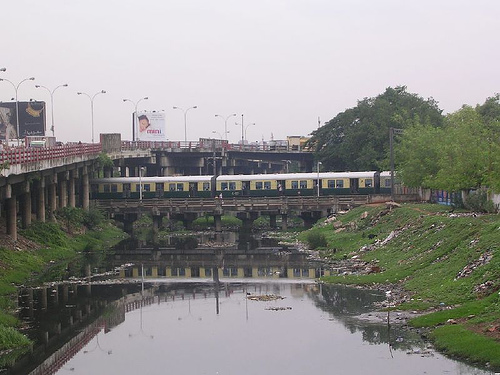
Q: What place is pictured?
A: It is a river.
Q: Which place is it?
A: It is a river.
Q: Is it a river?
A: Yes, it is a river.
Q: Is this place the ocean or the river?
A: It is the river.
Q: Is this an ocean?
A: No, it is a river.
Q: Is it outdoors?
A: Yes, it is outdoors.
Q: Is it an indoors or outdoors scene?
A: It is outdoors.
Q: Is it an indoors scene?
A: No, it is outdoors.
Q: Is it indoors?
A: No, it is outdoors.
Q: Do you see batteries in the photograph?
A: No, there are no batteries.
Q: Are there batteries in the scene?
A: No, there are no batteries.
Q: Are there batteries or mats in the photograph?
A: No, there are no batteries or mats.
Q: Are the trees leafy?
A: Yes, the trees are leafy.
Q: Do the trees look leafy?
A: Yes, the trees are leafy.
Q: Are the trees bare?
A: No, the trees are leafy.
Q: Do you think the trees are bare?
A: No, the trees are leafy.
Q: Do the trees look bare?
A: No, the trees are leafy.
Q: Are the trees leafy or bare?
A: The trees are leafy.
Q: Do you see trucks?
A: Yes, there is a truck.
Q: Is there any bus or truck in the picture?
A: Yes, there is a truck.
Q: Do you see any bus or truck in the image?
A: Yes, there is a truck.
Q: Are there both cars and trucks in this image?
A: Yes, there are both a truck and a car.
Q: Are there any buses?
A: No, there are no buses.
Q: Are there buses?
A: No, there are no buses.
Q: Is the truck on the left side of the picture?
A: Yes, the truck is on the left of the image.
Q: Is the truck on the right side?
A: No, the truck is on the left of the image.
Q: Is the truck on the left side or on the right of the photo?
A: The truck is on the left of the image.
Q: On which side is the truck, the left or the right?
A: The truck is on the left of the image.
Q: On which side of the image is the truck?
A: The truck is on the left of the image.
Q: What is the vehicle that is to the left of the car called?
A: The vehicle is a truck.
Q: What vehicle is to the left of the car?
A: The vehicle is a truck.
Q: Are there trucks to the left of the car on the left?
A: Yes, there is a truck to the left of the car.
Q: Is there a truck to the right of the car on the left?
A: No, the truck is to the left of the car.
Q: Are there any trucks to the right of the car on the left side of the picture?
A: No, the truck is to the left of the car.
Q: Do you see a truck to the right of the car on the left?
A: No, the truck is to the left of the car.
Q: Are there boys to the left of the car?
A: No, there is a truck to the left of the car.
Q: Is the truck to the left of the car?
A: Yes, the truck is to the left of the car.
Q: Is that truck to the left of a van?
A: No, the truck is to the left of the car.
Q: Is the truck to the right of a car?
A: No, the truck is to the left of a car.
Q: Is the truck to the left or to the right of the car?
A: The truck is to the left of the car.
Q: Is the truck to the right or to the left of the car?
A: The truck is to the left of the car.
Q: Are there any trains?
A: Yes, there is a train.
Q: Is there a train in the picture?
A: Yes, there is a train.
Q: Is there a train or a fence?
A: Yes, there is a train.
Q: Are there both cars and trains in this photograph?
A: Yes, there are both a train and a car.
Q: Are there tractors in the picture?
A: No, there are no tractors.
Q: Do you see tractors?
A: No, there are no tractors.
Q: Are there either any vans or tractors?
A: No, there are no tractors or vans.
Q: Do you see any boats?
A: No, there are no boats.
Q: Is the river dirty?
A: Yes, the river is dirty.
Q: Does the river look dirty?
A: Yes, the river is dirty.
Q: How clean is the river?
A: The river is dirty.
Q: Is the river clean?
A: No, the river is dirty.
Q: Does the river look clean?
A: No, the river is dirty.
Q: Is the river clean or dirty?
A: The river is dirty.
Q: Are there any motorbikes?
A: No, there are no motorbikes.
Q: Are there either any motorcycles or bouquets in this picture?
A: No, there are no motorcycles or bouquets.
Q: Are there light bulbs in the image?
A: No, there are no light bulbs.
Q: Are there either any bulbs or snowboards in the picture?
A: No, there are no bulbs or snowboards.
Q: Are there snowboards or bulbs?
A: No, there are no bulbs or snowboards.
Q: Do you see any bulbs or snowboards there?
A: No, there are no bulbs or snowboards.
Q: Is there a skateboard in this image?
A: No, there are no skateboards.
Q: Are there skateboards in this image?
A: No, there are no skateboards.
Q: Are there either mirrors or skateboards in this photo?
A: No, there are no skateboards or mirrors.